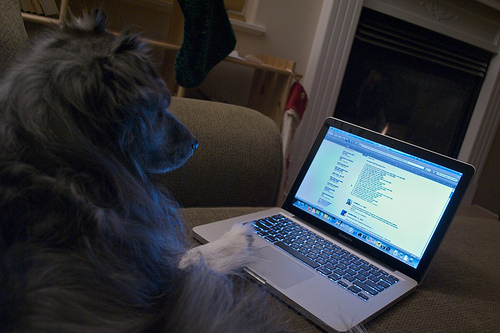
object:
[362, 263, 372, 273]
keyboard button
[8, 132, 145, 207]
neck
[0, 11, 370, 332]
dog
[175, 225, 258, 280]
paw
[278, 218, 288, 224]
button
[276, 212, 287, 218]
button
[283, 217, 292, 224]
button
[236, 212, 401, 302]
keyboard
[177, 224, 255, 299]
leg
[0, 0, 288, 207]
couch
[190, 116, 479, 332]
laptop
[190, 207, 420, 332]
base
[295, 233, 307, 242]
button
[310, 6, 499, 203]
fireplace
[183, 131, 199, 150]
nose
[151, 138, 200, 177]
mouth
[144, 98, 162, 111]
eye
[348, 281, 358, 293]
button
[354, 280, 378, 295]
button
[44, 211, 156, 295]
fur